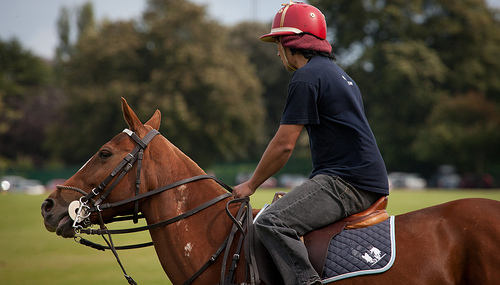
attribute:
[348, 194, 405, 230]
saddle — brown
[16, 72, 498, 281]
horse — brown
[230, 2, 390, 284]
man —  jockey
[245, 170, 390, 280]
jeans — black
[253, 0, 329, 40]
helmet — red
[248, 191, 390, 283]
saddle — brown , leather 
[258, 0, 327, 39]
helmet — red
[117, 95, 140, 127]
ear — brown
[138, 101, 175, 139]
ear — brown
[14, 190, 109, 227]
nose — dark, brown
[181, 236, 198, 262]
spots — white